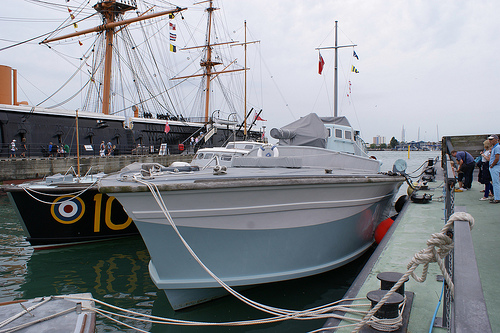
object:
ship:
[109, 105, 405, 305]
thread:
[140, 178, 370, 319]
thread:
[146, 195, 405, 327]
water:
[23, 253, 124, 288]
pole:
[77, 5, 261, 152]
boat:
[134, 159, 382, 285]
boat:
[14, 166, 128, 246]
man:
[481, 134, 484, 210]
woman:
[479, 151, 484, 207]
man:
[464, 141, 482, 191]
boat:
[108, 100, 411, 300]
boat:
[88, 117, 395, 303]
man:
[460, 141, 470, 154]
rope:
[142, 180, 372, 314]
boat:
[103, 133, 420, 286]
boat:
[84, 194, 132, 240]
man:
[457, 144, 476, 189]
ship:
[128, 92, 424, 300]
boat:
[99, 138, 403, 302]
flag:
[307, 42, 342, 79]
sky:
[367, 22, 437, 107]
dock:
[457, 181, 498, 297]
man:
[449, 146, 475, 188]